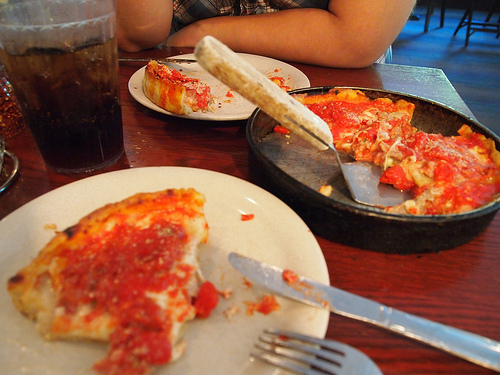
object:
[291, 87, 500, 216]
pizza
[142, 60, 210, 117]
pizza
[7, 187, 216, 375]
pizza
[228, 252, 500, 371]
knife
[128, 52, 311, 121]
plate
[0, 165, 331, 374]
plate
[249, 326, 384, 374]
fork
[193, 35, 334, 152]
handle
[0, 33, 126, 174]
liquid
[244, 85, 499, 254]
pan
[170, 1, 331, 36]
shirt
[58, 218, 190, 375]
sauce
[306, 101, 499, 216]
sauce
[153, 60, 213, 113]
sauce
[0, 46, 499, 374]
table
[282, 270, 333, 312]
sauce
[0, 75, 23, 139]
container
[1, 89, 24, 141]
red pepper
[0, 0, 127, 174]
glass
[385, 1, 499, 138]
floor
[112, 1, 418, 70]
man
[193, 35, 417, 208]
spatula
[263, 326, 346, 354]
tine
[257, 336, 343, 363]
tine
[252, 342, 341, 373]
tine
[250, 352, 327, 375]
tine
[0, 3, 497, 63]
building